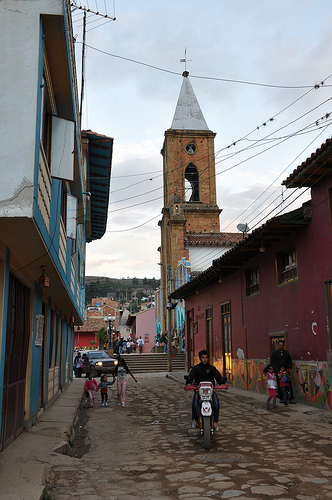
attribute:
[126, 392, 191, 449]
stones — gray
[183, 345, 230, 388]
man — young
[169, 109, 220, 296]
building — wall on the side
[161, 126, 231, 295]
building — wall on the side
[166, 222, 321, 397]
building — wall on the side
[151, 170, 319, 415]
building — wall on the side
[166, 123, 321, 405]
building — wall on the side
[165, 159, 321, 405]
building — wall on the side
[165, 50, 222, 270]
building — wall on the side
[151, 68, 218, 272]
building — window 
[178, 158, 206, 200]
building — window 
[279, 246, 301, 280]
building — window 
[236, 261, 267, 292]
building — window 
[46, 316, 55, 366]
building — window 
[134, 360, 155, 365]
stairway — step 